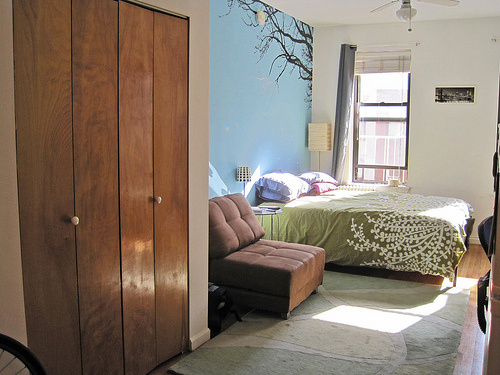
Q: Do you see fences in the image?
A: No, there are no fences.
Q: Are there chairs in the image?
A: Yes, there is a chair.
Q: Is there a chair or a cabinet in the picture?
A: Yes, there is a chair.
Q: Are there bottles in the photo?
A: No, there are no bottles.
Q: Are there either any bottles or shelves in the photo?
A: No, there are no bottles or shelves.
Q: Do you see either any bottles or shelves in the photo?
A: No, there are no bottles or shelves.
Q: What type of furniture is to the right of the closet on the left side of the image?
A: The piece of furniture is a chair.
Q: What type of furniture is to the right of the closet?
A: The piece of furniture is a chair.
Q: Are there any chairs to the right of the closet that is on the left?
A: Yes, there is a chair to the right of the closet.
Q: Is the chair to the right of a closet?
A: Yes, the chair is to the right of a closet.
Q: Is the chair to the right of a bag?
A: No, the chair is to the right of a closet.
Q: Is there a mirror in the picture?
A: No, there are no mirrors.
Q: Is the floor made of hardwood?
A: Yes, the floor is made of hardwood.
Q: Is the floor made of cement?
A: No, the floor is made of hardwood.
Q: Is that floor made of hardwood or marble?
A: The floor is made of hardwood.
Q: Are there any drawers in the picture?
A: No, there are no drawers.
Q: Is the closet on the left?
A: Yes, the closet is on the left of the image.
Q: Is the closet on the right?
A: No, the closet is on the left of the image.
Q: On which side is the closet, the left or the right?
A: The closet is on the left of the image.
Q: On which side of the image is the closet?
A: The closet is on the left of the image.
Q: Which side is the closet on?
A: The closet is on the left of the image.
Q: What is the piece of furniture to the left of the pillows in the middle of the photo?
A: The piece of furniture is a closet.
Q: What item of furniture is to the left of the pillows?
A: The piece of furniture is a closet.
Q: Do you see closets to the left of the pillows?
A: Yes, there is a closet to the left of the pillows.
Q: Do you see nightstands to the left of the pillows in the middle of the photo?
A: No, there is a closet to the left of the pillows.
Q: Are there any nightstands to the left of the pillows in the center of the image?
A: No, there is a closet to the left of the pillows.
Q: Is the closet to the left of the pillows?
A: Yes, the closet is to the left of the pillows.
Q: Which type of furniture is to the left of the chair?
A: The piece of furniture is a closet.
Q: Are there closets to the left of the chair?
A: Yes, there is a closet to the left of the chair.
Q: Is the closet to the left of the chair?
A: Yes, the closet is to the left of the chair.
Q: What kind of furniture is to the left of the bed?
A: The piece of furniture is a closet.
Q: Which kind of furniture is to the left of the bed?
A: The piece of furniture is a closet.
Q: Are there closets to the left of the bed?
A: Yes, there is a closet to the left of the bed.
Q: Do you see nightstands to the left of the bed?
A: No, there is a closet to the left of the bed.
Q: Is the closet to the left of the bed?
A: Yes, the closet is to the left of the bed.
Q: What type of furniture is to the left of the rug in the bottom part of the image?
A: The piece of furniture is a closet.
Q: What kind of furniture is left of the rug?
A: The piece of furniture is a closet.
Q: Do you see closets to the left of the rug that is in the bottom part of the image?
A: Yes, there is a closet to the left of the rug.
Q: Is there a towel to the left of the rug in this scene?
A: No, there is a closet to the left of the rug.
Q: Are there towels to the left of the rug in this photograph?
A: No, there is a closet to the left of the rug.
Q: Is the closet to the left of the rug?
A: Yes, the closet is to the left of the rug.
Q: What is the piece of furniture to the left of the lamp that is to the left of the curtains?
A: The piece of furniture is a closet.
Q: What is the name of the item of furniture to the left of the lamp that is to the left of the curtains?
A: The piece of furniture is a closet.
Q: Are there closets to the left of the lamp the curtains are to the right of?
A: Yes, there is a closet to the left of the lamp.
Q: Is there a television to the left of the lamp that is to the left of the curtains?
A: No, there is a closet to the left of the lamp.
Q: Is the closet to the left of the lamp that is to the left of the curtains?
A: Yes, the closet is to the left of the lamp.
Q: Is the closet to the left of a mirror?
A: No, the closet is to the left of the lamp.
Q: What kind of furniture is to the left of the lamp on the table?
A: The piece of furniture is a closet.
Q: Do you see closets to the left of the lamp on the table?
A: Yes, there is a closet to the left of the lamp.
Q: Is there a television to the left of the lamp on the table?
A: No, there is a closet to the left of the lamp.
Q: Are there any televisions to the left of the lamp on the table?
A: No, there is a closet to the left of the lamp.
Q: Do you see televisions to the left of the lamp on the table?
A: No, there is a closet to the left of the lamp.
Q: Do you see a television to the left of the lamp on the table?
A: No, there is a closet to the left of the lamp.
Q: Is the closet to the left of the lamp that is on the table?
A: Yes, the closet is to the left of the lamp.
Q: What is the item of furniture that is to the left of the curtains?
A: The piece of furniture is a closet.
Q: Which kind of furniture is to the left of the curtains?
A: The piece of furniture is a closet.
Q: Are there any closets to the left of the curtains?
A: Yes, there is a closet to the left of the curtains.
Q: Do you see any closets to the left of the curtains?
A: Yes, there is a closet to the left of the curtains.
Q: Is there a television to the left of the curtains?
A: No, there is a closet to the left of the curtains.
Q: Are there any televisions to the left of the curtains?
A: No, there is a closet to the left of the curtains.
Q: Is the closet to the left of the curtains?
A: Yes, the closet is to the left of the curtains.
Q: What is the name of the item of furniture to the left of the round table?
A: The piece of furniture is a closet.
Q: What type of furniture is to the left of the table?
A: The piece of furniture is a closet.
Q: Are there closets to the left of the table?
A: Yes, there is a closet to the left of the table.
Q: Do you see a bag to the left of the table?
A: No, there is a closet to the left of the table.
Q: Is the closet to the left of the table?
A: Yes, the closet is to the left of the table.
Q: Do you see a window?
A: Yes, there is a window.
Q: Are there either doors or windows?
A: Yes, there is a window.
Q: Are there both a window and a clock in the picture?
A: No, there is a window but no clocks.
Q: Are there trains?
A: No, there are no trains.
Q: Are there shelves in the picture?
A: No, there are no shelves.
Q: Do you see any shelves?
A: No, there are no shelves.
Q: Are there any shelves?
A: No, there are no shelves.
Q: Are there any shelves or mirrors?
A: No, there are no shelves or mirrors.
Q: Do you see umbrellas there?
A: No, there are no umbrellas.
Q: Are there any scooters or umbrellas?
A: No, there are no umbrellas or scooters.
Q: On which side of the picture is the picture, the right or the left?
A: The picture is on the right of the image.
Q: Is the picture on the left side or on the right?
A: The picture is on the right of the image.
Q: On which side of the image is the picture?
A: The picture is on the right of the image.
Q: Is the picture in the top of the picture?
A: Yes, the picture is in the top of the image.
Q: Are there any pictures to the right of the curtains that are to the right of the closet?
A: Yes, there is a picture to the right of the curtains.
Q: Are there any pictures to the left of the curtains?
A: No, the picture is to the right of the curtains.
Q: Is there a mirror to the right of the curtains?
A: No, there is a picture to the right of the curtains.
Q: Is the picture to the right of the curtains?
A: Yes, the picture is to the right of the curtains.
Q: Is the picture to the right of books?
A: No, the picture is to the right of the curtains.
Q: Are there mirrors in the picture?
A: No, there are no mirrors.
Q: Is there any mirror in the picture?
A: No, there are no mirrors.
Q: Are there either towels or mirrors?
A: No, there are no mirrors or towels.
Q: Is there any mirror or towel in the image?
A: No, there are no mirrors or towels.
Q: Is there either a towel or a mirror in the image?
A: No, there are no mirrors or towels.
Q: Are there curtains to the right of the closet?
A: Yes, there are curtains to the right of the closet.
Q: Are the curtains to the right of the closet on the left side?
A: Yes, the curtains are to the right of the closet.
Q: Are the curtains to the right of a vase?
A: No, the curtains are to the right of the closet.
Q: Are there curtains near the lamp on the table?
A: Yes, there are curtains near the lamp.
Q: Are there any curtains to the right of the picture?
A: No, the curtains are to the left of the picture.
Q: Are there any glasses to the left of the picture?
A: No, there are curtains to the left of the picture.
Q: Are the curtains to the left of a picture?
A: Yes, the curtains are to the left of a picture.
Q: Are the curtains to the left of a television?
A: No, the curtains are to the left of a picture.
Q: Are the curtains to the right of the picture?
A: No, the curtains are to the left of the picture.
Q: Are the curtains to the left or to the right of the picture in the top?
A: The curtains are to the left of the picture.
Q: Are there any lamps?
A: Yes, there is a lamp.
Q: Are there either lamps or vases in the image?
A: Yes, there is a lamp.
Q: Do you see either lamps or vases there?
A: Yes, there is a lamp.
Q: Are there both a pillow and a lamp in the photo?
A: Yes, there are both a lamp and a pillow.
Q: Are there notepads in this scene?
A: No, there are no notepads.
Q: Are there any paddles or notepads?
A: No, there are no notepads or paddles.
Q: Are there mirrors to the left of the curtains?
A: No, there is a lamp to the left of the curtains.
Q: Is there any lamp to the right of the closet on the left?
A: Yes, there is a lamp to the right of the closet.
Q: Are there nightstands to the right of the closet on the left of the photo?
A: No, there is a lamp to the right of the closet.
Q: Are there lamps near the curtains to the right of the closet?
A: Yes, there is a lamp near the curtains.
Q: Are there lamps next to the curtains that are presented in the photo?
A: Yes, there is a lamp next to the curtains.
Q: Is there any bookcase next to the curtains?
A: No, there is a lamp next to the curtains.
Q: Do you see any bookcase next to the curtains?
A: No, there is a lamp next to the curtains.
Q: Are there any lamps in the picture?
A: Yes, there is a lamp.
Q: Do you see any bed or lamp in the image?
A: Yes, there is a lamp.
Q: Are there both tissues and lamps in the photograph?
A: No, there is a lamp but no tissues.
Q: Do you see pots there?
A: No, there are no pots.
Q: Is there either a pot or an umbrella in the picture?
A: No, there are no pots or umbrellas.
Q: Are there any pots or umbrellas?
A: No, there are no pots or umbrellas.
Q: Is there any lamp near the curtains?
A: Yes, there is a lamp near the curtains.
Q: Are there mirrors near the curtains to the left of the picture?
A: No, there is a lamp near the curtains.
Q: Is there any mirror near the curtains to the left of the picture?
A: No, there is a lamp near the curtains.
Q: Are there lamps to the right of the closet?
A: Yes, there is a lamp to the right of the closet.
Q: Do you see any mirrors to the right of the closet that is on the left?
A: No, there is a lamp to the right of the closet.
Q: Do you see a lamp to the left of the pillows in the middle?
A: Yes, there is a lamp to the left of the pillows.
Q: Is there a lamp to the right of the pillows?
A: No, the lamp is to the left of the pillows.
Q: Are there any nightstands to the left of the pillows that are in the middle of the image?
A: No, there is a lamp to the left of the pillows.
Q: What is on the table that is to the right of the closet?
A: The lamp is on the table.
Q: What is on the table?
A: The lamp is on the table.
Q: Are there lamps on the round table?
A: Yes, there is a lamp on the table.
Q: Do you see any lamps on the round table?
A: Yes, there is a lamp on the table.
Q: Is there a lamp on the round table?
A: Yes, there is a lamp on the table.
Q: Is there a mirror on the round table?
A: No, there is a lamp on the table.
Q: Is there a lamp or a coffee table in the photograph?
A: Yes, there is a lamp.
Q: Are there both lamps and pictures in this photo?
A: Yes, there are both a lamp and a picture.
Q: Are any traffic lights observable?
A: No, there are no traffic lights.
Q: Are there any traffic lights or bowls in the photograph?
A: No, there are no traffic lights or bowls.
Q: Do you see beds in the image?
A: Yes, there is a bed.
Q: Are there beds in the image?
A: Yes, there is a bed.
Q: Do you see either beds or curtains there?
A: Yes, there is a bed.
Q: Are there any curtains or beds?
A: Yes, there is a bed.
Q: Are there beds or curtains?
A: Yes, there is a bed.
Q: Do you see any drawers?
A: No, there are no drawers.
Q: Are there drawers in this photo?
A: No, there are no drawers.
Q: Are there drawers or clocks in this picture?
A: No, there are no drawers or clocks.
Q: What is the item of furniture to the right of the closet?
A: The piece of furniture is a bed.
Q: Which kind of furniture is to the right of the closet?
A: The piece of furniture is a bed.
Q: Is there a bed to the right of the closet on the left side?
A: Yes, there is a bed to the right of the closet.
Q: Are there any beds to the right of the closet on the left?
A: Yes, there is a bed to the right of the closet.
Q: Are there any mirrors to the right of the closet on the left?
A: No, there is a bed to the right of the closet.